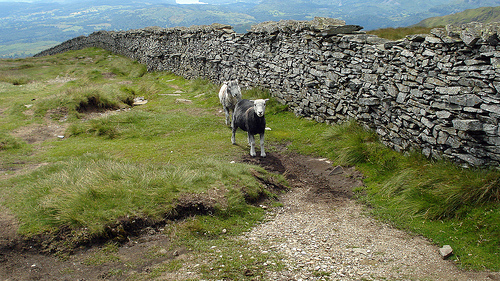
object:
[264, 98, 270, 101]
left horn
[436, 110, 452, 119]
rock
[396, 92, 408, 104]
rock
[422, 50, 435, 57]
rock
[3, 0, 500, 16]
hills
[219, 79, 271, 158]
sheep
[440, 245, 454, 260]
rock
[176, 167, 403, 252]
ground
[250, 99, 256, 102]
horn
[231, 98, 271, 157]
goat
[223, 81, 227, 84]
horn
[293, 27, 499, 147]
wall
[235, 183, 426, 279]
gravel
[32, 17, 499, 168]
fence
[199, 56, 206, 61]
stone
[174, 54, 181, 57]
stone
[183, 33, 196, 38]
stone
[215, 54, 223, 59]
stone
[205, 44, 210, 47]
stone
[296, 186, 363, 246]
ground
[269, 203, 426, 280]
ground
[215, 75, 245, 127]
sheep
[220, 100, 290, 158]
sheep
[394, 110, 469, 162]
ground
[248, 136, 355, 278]
ground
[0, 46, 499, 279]
ground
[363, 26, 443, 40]
grass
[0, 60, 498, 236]
grass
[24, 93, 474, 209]
base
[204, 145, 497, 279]
path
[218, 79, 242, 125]
goat